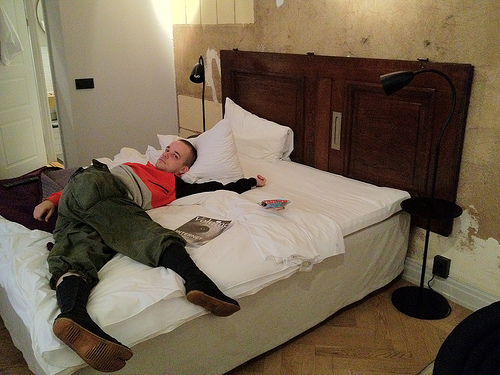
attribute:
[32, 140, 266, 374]
man — sprawled, twisted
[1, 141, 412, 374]
bed — white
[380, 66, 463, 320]
lamp — black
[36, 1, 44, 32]
mirror — oval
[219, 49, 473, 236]
headboard — wooden, large, old, brown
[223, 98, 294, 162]
pillow — white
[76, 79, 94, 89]
switch — black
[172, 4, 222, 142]
wall — unpainted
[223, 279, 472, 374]
floor — wooden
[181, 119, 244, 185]
pillow — white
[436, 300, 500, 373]
table — black, round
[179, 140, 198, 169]
hair — short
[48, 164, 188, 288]
pants — green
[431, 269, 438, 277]
outlet — black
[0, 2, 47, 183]
door — open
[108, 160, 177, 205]
shirt — red